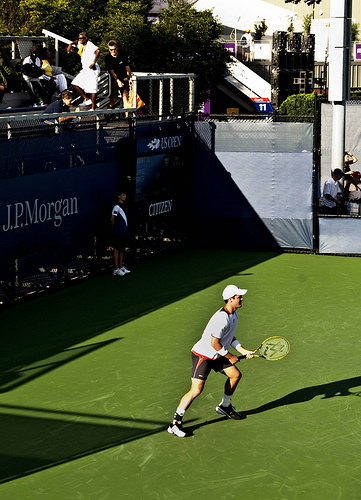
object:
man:
[66, 27, 102, 113]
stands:
[0, 29, 197, 131]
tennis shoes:
[166, 419, 187, 439]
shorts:
[190, 347, 237, 384]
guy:
[166, 284, 254, 439]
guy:
[107, 187, 132, 277]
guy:
[104, 37, 132, 110]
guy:
[40, 87, 74, 125]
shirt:
[190, 308, 237, 363]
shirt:
[110, 201, 129, 234]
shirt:
[323, 175, 343, 208]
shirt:
[75, 41, 100, 69]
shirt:
[105, 54, 131, 91]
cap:
[221, 283, 246, 303]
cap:
[244, 28, 249, 34]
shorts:
[69, 68, 100, 95]